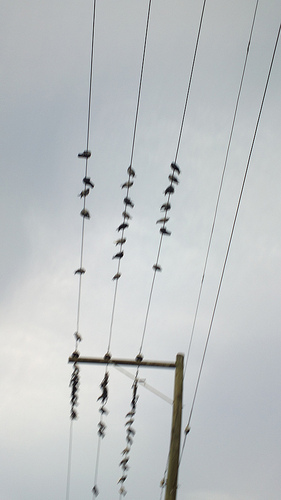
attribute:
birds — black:
[74, 145, 188, 279]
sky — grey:
[4, 11, 279, 493]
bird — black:
[74, 149, 95, 159]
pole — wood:
[163, 356, 188, 498]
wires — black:
[61, 180, 223, 424]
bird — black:
[154, 256, 164, 277]